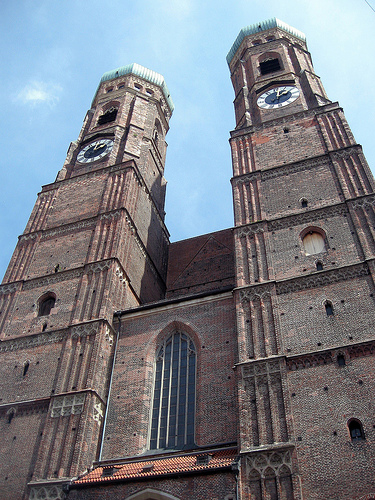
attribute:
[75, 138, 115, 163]
clock — white, black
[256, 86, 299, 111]
clock — white, black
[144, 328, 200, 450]
window — large, ornate, arched, tall, glass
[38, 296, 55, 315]
window — small, ornate, arched, glass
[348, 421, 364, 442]
window — small, ornate, glass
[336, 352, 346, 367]
window — small, ornate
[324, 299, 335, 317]
window — small, ornate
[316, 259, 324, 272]
window — small, ornate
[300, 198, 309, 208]
window — small, ornate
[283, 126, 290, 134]
window — small, ornate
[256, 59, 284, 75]
window — small, ornate, glass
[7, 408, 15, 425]
window — small, ornate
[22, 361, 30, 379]
window — small, ornate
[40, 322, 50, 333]
window — small, ornate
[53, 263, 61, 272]
window — small, ornate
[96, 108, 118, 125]
window — small, ornate, glass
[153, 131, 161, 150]
window — small, ornate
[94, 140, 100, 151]
hand — gold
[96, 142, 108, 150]
hand — gold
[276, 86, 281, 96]
hand — gold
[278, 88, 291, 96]
hand — gold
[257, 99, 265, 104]
roman numeral — black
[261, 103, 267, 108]
roman numeral — black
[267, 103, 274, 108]
roman numeral — black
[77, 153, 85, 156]
roman numeral — black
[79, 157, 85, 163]
roman numeral — black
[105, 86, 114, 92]
window — arched, high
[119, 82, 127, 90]
window — arched, high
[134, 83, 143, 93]
window — arched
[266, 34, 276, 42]
window — arched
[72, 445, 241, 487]
tile — clay, red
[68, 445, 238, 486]
roof — red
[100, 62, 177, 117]
parapet — decorative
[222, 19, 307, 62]
parapet — decorative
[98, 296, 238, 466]
wall — brick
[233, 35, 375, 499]
wall — brick, brown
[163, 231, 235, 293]
wall — brick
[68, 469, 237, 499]
wall — brick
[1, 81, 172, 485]
wall — brick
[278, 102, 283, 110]
roman numeral — gold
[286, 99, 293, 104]
roman numeral — gold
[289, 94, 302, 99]
roman numeral — gold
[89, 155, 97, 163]
roman numeral — gold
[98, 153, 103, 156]
roman numeral — gold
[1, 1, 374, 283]
sky — blue, white, clear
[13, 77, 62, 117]
cloud — tiny, thin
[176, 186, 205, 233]
cloud — tiny, thin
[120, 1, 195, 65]
cloud — tiny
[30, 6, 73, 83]
cloud — tiny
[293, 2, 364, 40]
cloud — tiny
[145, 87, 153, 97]
window — small, high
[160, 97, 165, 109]
window — small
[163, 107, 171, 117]
window — small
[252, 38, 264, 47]
window — small, high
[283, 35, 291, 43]
window — small, high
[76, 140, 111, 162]
dial — round, gold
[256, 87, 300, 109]
dial — round, gold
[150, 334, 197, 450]
glass — stained